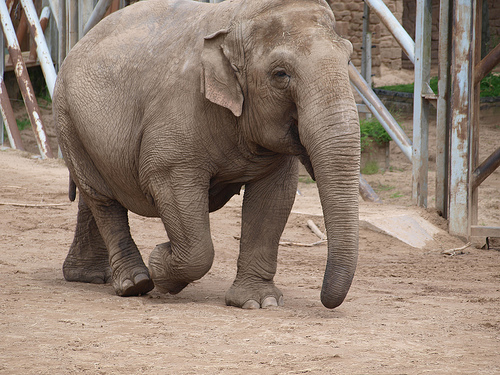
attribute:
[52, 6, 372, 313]
elephant — wrinkly, Gray 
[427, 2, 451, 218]
blue sky — metal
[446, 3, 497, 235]
pole — long, metal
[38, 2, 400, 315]
elephant — grey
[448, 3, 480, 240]
metal pole — long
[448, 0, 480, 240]
column — rusty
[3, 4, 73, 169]
fence — Rusted metal poles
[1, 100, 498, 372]
dirt — brown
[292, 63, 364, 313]
trunk — wrinkled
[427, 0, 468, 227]
pole — long